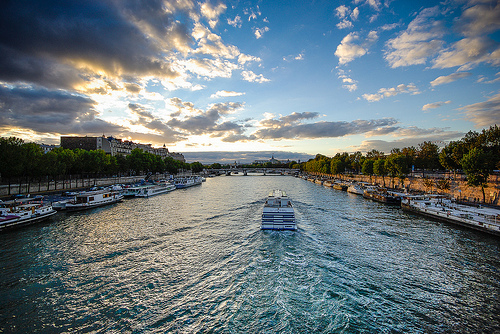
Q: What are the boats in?
A: A river.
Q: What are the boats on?
A: Water.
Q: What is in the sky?
A: Clouds.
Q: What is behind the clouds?
A: The sun.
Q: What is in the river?
A: Boats.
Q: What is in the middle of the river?
A: A boat.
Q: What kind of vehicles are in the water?
A: Boats.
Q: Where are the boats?
A: In the water.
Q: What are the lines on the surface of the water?
A: Ripples.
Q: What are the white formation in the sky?
A: Clouds.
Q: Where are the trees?
A: Bordering the body of water.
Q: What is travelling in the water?
A: Boat.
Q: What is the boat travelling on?
A: Water.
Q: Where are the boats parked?
A: Along the shore.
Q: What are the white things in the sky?
A: Clouds.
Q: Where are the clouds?
A: Sky.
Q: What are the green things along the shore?
A: Trees.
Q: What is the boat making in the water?
A: Waves.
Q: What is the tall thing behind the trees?
A: Building.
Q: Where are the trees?
A: Along the shore.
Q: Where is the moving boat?
A: Water.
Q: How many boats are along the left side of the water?
A: Four.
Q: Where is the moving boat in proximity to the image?
A: The center.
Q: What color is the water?
A: Blue.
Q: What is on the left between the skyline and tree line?
A: Buildings.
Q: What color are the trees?
A: Green.